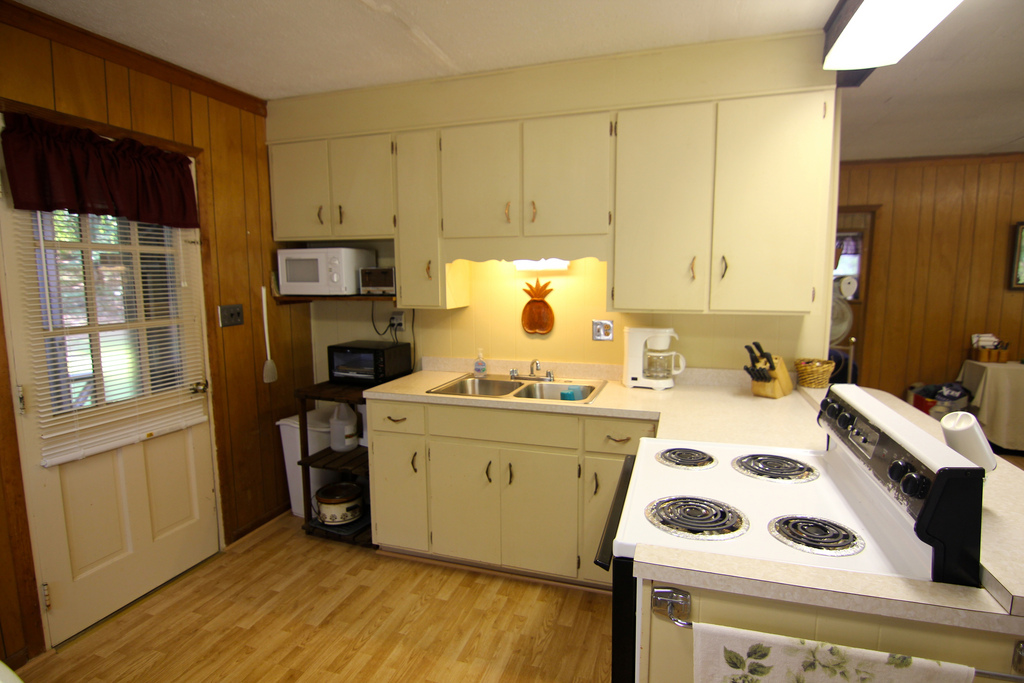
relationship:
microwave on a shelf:
[273, 247, 353, 297] [277, 297, 388, 302]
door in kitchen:
[16, 104, 226, 653] [35, 24, 986, 653]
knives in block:
[746, 342, 768, 379] [738, 342, 795, 401]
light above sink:
[517, 260, 572, 278] [435, 362, 524, 406]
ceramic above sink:
[524, 280, 555, 341] [435, 367, 604, 409]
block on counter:
[755, 354, 792, 398] [366, 358, 1021, 622]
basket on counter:
[792, 357, 836, 389] [381, 356, 999, 640]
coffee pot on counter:
[621, 324, 689, 392] [370, 345, 809, 434]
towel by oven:
[692, 623, 973, 680] [610, 436, 1021, 674]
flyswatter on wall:
[258, 284, 282, 385] [1, 4, 297, 651]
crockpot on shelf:
[268, 357, 405, 602] [267, 292, 414, 561]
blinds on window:
[18, 217, 209, 470] [33, 211, 202, 440]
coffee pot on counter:
[615, 321, 693, 393] [364, 367, 831, 452]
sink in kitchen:
[415, 360, 619, 404] [35, 24, 986, 653]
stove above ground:
[583, 406, 940, 607] [117, 566, 601, 677]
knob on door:
[184, 362, 228, 410] [10, 180, 240, 639]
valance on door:
[10, 89, 207, 221] [10, 180, 240, 639]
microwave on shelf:
[276, 246, 377, 296] [274, 285, 389, 311]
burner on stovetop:
[642, 479, 742, 546] [601, 434, 1021, 649]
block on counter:
[750, 353, 793, 400] [356, 356, 843, 441]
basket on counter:
[780, 352, 847, 392] [356, 345, 873, 460]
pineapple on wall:
[505, 274, 575, 344] [296, 244, 839, 407]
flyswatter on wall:
[251, 274, 299, 393] [2, 13, 322, 627]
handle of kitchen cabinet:
[709, 252, 738, 289] [713, 106, 824, 314]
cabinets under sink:
[354, 409, 596, 595] [425, 366, 607, 403]